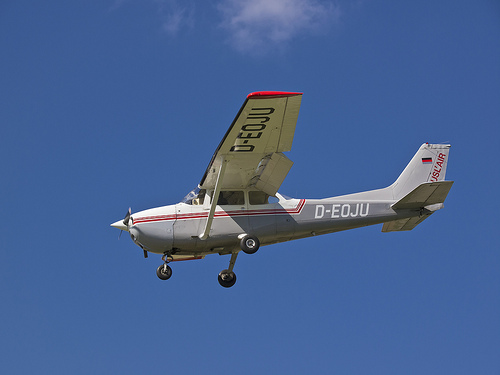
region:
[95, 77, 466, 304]
An airplane in the air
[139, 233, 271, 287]
Wheels on an airplane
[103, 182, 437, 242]
A gray plane with red stripes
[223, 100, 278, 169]
Letters under the wing of a plane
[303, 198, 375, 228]
Letters on the side of a plane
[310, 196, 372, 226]
White letters on a plane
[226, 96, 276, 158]
Black letter on the wing of a plane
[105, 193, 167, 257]
A propeller on an airplane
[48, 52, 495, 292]
Blue sky behind a plane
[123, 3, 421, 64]
A small cloud in the sky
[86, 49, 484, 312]
small plane flying in air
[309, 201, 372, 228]
lettering on side of plane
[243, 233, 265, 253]
small black landing wheel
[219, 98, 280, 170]
lettering on wing of plane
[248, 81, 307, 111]
red tip to wing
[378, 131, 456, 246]
tail fins of plane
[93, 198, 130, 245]
front propeller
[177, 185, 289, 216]
side windows on plane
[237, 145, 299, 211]
movable wind flap on plane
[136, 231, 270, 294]
landing gears of plane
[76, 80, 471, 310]
Plane flying in the blue sky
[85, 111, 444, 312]
A small plane flying in the sky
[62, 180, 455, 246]
A gray red & white plane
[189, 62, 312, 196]
Wing of plane with numbers on it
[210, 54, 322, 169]
Plane number is D-E0JU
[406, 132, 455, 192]
Tail of plane with flag on it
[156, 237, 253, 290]
Wheels of plane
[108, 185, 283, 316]
Three wheels on plane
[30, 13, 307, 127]
Blue sky with a wisping of clouds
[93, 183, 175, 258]
Nose of the plane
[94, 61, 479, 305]
a red gray and white plane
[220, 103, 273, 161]
numbers on left wing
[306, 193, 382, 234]
numbers on rear body of plane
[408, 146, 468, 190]
name on rear tail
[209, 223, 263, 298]
wheels on bottom of plane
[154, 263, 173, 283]
front wheel of plane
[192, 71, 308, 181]
red tip wing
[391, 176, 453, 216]
rear wing of plan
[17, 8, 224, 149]
clear blue skys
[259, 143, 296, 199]
flip on a air plane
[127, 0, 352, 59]
A cloud in the sky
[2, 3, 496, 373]
A clear blue sky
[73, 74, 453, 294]
A grey, red, and white airplane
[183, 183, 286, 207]
the cockpit of an airplane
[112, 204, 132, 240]
The propeller of an airplane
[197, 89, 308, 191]
The left wind of an airplane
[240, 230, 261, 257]
A wheel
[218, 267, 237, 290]
A wheel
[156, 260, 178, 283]
A wheel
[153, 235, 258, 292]
The landing gear of a plane